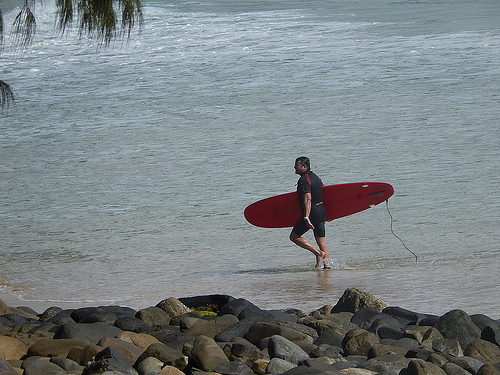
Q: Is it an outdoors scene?
A: Yes, it is outdoors.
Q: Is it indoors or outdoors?
A: It is outdoors.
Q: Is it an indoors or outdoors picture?
A: It is outdoors.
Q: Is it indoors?
A: No, it is outdoors.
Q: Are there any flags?
A: No, there are no flags.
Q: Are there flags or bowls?
A: No, there are no flags or bowls.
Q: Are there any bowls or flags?
A: No, there are no flags or bowls.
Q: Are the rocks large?
A: Yes, the rocks are large.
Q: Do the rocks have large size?
A: Yes, the rocks are large.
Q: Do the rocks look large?
A: Yes, the rocks are large.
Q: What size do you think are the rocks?
A: The rocks are large.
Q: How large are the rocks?
A: The rocks are large.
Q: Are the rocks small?
A: No, the rocks are large.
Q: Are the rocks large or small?
A: The rocks are large.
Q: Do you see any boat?
A: No, there are no boats.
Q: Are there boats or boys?
A: No, there are no boats or boys.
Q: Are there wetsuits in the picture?
A: Yes, there is a wetsuit.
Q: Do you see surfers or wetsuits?
A: Yes, there is a wetsuit.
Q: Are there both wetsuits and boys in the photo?
A: No, there is a wetsuit but no boys.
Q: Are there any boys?
A: No, there are no boys.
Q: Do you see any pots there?
A: No, there are no pots.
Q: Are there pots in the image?
A: No, there are no pots.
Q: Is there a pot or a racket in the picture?
A: No, there are no pots or rackets.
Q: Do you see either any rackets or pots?
A: No, there are no pots or rackets.